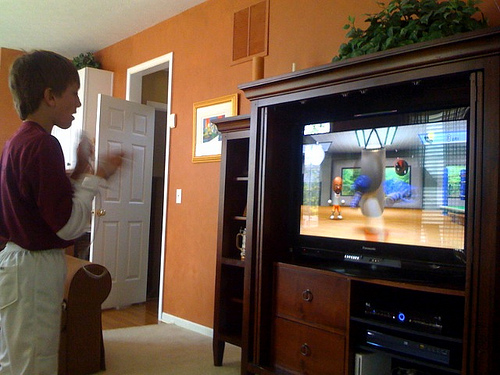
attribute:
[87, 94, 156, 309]
door — open, white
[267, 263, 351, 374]
drawers — brown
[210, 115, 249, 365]
book shelf — brown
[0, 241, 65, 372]
pants — white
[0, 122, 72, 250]
shirt — maroon, burgundy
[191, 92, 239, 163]
picture — in a gold frame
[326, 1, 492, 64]
plant — green, large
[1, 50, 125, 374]
boy — standing, playing a game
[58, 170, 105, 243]
sleeve — white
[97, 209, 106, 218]
door knob — brass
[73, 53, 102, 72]
plant — green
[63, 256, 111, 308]
arm of sofa — brown, large